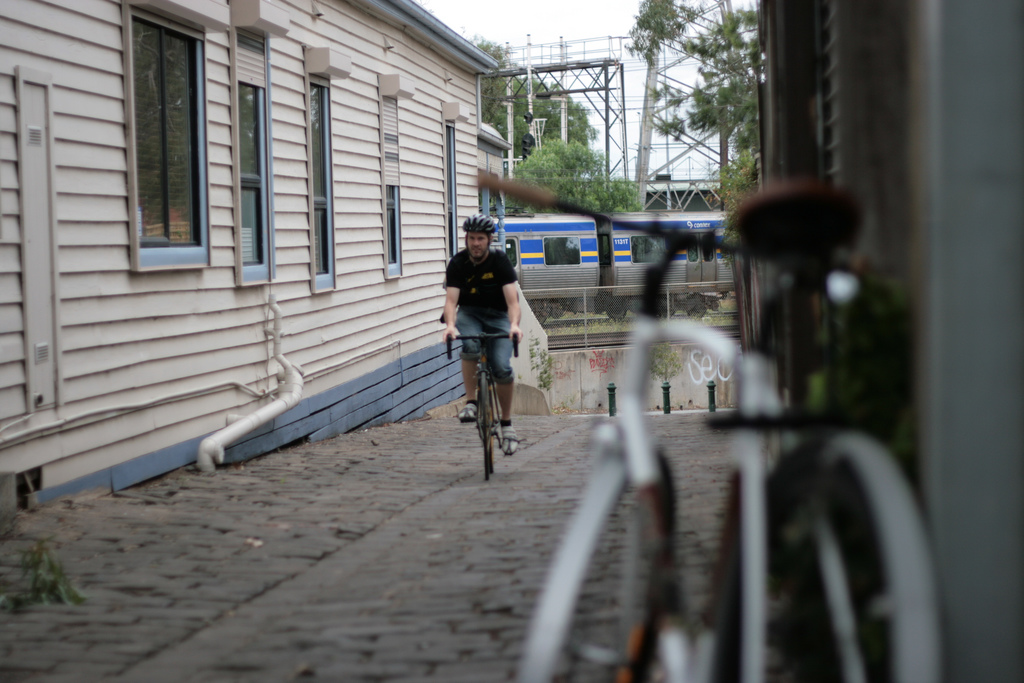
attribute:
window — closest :
[108, 2, 225, 278]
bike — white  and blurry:
[472, 160, 941, 670]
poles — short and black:
[588, 371, 729, 414]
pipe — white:
[185, 290, 316, 472]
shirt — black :
[446, 247, 520, 321]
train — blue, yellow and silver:
[491, 212, 747, 302]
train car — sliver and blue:
[519, 144, 675, 335]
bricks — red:
[195, 455, 574, 656]